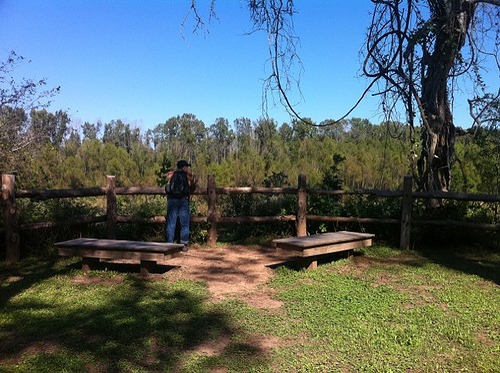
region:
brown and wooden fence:
[250, 147, 344, 236]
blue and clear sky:
[111, 1, 181, 113]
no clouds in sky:
[100, 10, 170, 90]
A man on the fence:
[158, 149, 217, 249]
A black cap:
[171, 152, 196, 169]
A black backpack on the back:
[163, 167, 195, 214]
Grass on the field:
[315, 270, 439, 366]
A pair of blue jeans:
[162, 202, 195, 239]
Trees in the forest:
[216, 129, 321, 169]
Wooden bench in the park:
[284, 218, 377, 258]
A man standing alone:
[148, 144, 204, 256]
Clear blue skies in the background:
[109, 40, 197, 112]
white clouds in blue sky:
[300, 81, 351, 129]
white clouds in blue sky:
[55, 58, 95, 80]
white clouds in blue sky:
[155, 38, 183, 78]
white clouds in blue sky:
[174, 46, 214, 71]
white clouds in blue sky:
[320, 16, 350, 40]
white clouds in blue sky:
[301, 46, 335, 93]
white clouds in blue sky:
[170, 45, 222, 105]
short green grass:
[311, 278, 349, 309]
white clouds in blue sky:
[50, 55, 128, 97]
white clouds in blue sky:
[181, 28, 215, 66]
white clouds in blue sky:
[124, 58, 161, 90]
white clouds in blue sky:
[58, 45, 113, 76]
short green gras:
[322, 293, 372, 324]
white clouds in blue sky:
[127, 71, 172, 88]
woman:
[150, 149, 202, 247]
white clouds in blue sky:
[120, 22, 165, 53]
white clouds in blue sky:
[24, 33, 96, 74]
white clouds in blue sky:
[317, 43, 351, 77]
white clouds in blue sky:
[198, 59, 260, 106]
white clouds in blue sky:
[75, 32, 139, 63]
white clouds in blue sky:
[147, 42, 178, 67]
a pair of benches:
[46, 225, 390, 275]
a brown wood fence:
[23, 150, 497, 277]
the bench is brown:
[41, 215, 186, 291]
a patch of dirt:
[148, 220, 296, 328]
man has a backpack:
[164, 159, 196, 201]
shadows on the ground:
[23, 225, 259, 367]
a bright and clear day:
[8, 13, 498, 353]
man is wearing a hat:
[172, 153, 197, 173]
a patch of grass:
[272, 230, 490, 372]